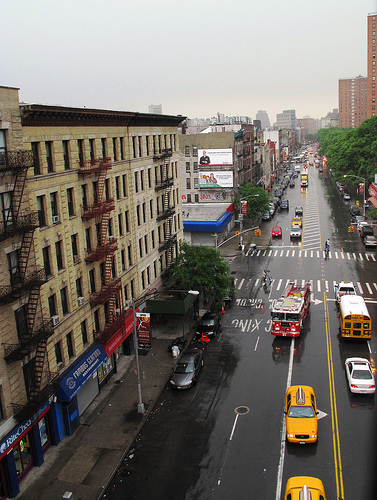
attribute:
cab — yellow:
[283, 380, 320, 449]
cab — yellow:
[280, 477, 336, 498]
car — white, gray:
[341, 355, 377, 396]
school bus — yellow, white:
[336, 292, 373, 345]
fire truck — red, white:
[270, 281, 311, 338]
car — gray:
[171, 347, 202, 388]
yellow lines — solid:
[322, 288, 344, 499]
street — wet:
[266, 174, 375, 473]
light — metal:
[122, 288, 206, 431]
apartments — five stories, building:
[18, 103, 186, 409]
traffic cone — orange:
[220, 303, 226, 314]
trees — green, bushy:
[317, 117, 376, 189]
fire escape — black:
[2, 145, 54, 421]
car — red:
[270, 223, 284, 242]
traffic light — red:
[251, 226, 264, 244]